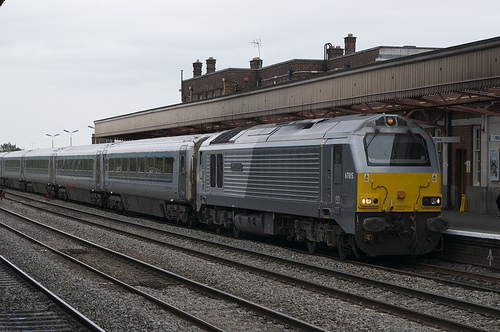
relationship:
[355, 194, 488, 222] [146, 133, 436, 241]
lights on train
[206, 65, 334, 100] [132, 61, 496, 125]
roof of building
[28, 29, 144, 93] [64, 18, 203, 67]
clouds in sky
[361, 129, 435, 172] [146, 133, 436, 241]
window on train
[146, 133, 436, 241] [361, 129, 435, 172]
train with window